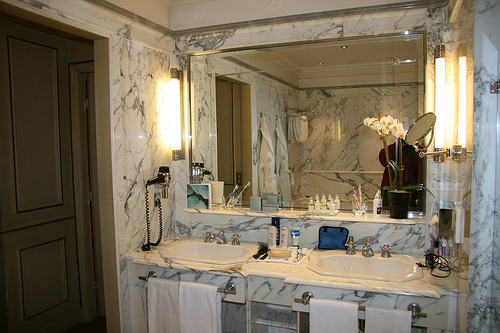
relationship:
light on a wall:
[168, 67, 182, 161] [112, 55, 147, 174]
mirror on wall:
[187, 33, 427, 220] [115, 5, 495, 252]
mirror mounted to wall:
[190, 57, 435, 226] [109, 44, 189, 328]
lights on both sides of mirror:
[152, 46, 484, 172] [193, 52, 455, 205]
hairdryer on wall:
[130, 157, 185, 244] [115, 42, 180, 253]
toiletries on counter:
[263, 213, 300, 259] [155, 230, 448, 295]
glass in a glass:
[222, 170, 253, 215] [351, 181, 367, 219]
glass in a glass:
[361, 188, 362, 195] [351, 181, 367, 219]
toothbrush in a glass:
[232, 176, 249, 192] [351, 181, 367, 219]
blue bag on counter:
[313, 225, 351, 250] [128, 234, 466, 299]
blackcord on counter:
[416, 238, 456, 278] [135, 230, 452, 317]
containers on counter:
[260, 212, 303, 252] [128, 234, 466, 299]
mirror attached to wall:
[403, 112, 435, 144] [468, 77, 483, 307]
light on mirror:
[165, 68, 185, 161] [187, 33, 427, 220]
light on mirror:
[431, 39, 451, 163] [187, 33, 427, 220]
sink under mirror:
[165, 224, 307, 272] [217, 41, 498, 231]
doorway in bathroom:
[0, 3, 105, 328] [4, 0, 496, 329]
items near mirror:
[422, 204, 468, 279] [185, 50, 428, 220]